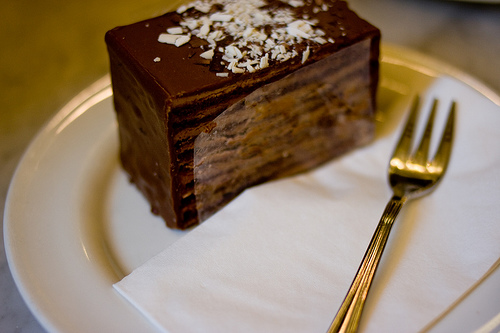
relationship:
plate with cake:
[4, 44, 499, 329] [105, 0, 381, 226]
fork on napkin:
[329, 94, 459, 331] [115, 75, 499, 330]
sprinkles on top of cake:
[155, 2, 332, 76] [105, 0, 381, 226]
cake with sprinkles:
[105, 0, 381, 226] [155, 2, 332, 76]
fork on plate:
[329, 94, 459, 331] [4, 44, 499, 329]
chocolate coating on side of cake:
[105, 38, 175, 227] [105, 0, 381, 226]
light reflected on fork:
[389, 153, 445, 176] [329, 94, 459, 331]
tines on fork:
[389, 94, 457, 200] [329, 94, 459, 331]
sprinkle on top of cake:
[155, 56, 162, 64] [105, 0, 381, 226]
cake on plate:
[105, 0, 381, 226] [4, 44, 499, 329]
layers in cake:
[174, 37, 373, 233] [105, 0, 381, 226]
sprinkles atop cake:
[155, 2, 332, 76] [105, 0, 381, 226]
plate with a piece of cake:
[4, 44, 499, 329] [105, 0, 381, 226]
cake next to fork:
[105, 0, 381, 226] [329, 94, 459, 331]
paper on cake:
[195, 39, 372, 229] [105, 0, 381, 226]